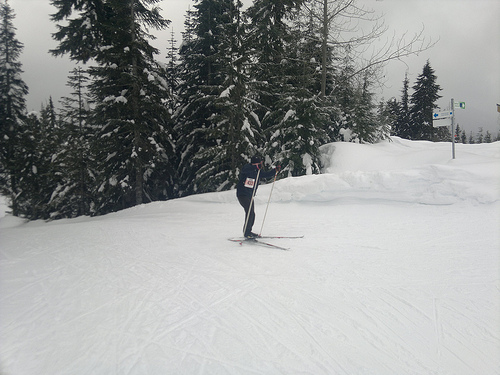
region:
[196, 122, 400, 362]
the man is skating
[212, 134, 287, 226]
the man is skating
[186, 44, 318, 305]
the man is skating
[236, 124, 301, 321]
the man is skating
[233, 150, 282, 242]
The person on skis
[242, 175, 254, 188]
The number bib on the front of the skier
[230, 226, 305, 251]
The skis the person is on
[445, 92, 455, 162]
The pole holding the sign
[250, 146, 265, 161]
The black beanie on the skier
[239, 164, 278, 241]
The poles of the skier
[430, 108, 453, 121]
The blue and white sign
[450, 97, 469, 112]
The white and green sign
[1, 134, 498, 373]
The snow on the ground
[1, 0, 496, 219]
The snow covered with trees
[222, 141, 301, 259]
the man is skiing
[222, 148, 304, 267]
the mans skies are crossed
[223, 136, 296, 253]
the man is wearing a black snow suit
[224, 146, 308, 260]
the man has a number on his stomach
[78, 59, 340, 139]
the trees are snow covered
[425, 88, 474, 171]
the sign tells where to go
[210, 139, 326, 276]
the skier is using his poles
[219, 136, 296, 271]
he has two poles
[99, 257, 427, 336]
the ground is snow covered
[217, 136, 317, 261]
the skier is getting started down the mountain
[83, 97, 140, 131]
the leaves has snow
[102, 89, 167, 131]
the leaves has snow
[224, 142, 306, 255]
The skier in the photo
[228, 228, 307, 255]
The skis of the skier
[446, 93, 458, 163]
The pole holding the signs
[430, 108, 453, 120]
The white and blue sign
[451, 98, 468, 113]
The green and white sign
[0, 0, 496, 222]
The pine trees behind the skier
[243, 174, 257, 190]
The number bib on the skier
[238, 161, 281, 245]
The poles held by the skier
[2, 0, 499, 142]
The cloudy sky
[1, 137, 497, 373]
The snow covering the ground